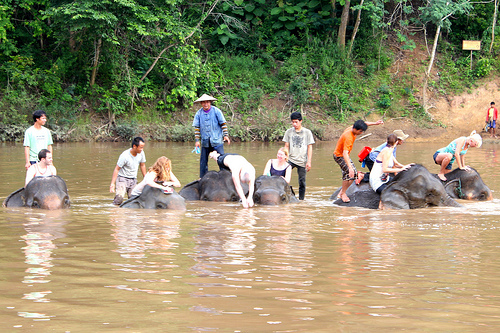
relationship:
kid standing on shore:
[484, 100, 498, 139] [7, 102, 499, 143]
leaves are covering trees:
[70, 8, 119, 40] [9, 7, 200, 110]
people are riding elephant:
[19, 91, 496, 168] [327, 160, 460, 210]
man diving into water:
[206, 148, 258, 207] [227, 207, 354, 284]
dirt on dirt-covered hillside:
[395, 47, 420, 70] [371, 32, 498, 148]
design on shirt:
[284, 131, 304, 148] [279, 124, 314, 173]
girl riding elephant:
[125, 152, 187, 202] [429, 165, 493, 201]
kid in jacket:
[486, 94, 498, 135] [478, 102, 498, 123]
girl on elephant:
[433, 131, 481, 180] [434, 161, 493, 204]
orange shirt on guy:
[333, 127, 358, 160] [332, 115, 382, 202]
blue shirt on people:
[190, 109, 233, 140] [191, 92, 230, 183]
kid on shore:
[484, 100, 498, 139] [7, 102, 499, 143]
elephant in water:
[327, 160, 460, 210] [116, 216, 441, 321]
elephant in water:
[327, 160, 460, 210] [159, 212, 355, 308]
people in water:
[163, 99, 405, 186] [159, 212, 355, 308]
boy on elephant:
[329, 112, 386, 206] [329, 159, 463, 216]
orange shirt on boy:
[331, 124, 355, 157] [329, 112, 386, 206]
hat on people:
[190, 88, 217, 105] [191, 92, 230, 183]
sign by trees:
[455, 38, 485, 70] [1, 0, 498, 122]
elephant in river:
[0, 175, 72, 212] [0, 135, 500, 328]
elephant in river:
[115, 183, 187, 210] [0, 135, 500, 328]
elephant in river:
[176, 168, 248, 205] [0, 135, 500, 328]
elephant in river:
[252, 173, 299, 205] [0, 135, 500, 328]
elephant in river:
[335, 160, 457, 208] [0, 135, 500, 328]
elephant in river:
[433, 168, 491, 198] [0, 135, 500, 328]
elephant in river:
[115, 183, 182, 213] [0, 135, 500, 328]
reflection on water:
[11, 203, 333, 279] [6, 203, 495, 332]